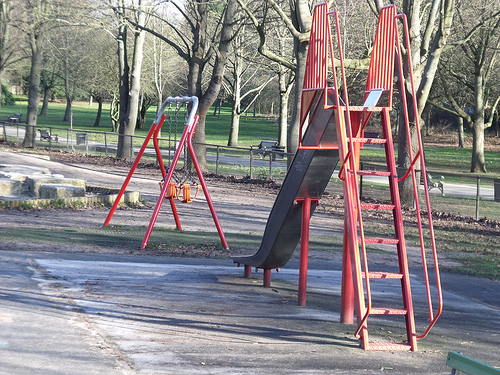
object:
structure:
[0, 162, 141, 211]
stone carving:
[8, 173, 87, 199]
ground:
[0, 97, 497, 375]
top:
[444, 348, 500, 375]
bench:
[443, 345, 500, 374]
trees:
[95, 45, 108, 78]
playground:
[1, 124, 500, 375]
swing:
[97, 94, 230, 251]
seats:
[158, 181, 182, 199]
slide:
[228, 0, 447, 356]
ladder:
[292, 2, 446, 355]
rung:
[347, 137, 387, 144]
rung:
[356, 170, 391, 176]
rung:
[354, 204, 395, 210]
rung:
[361, 271, 405, 279]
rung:
[365, 307, 408, 315]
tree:
[0, 0, 69, 151]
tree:
[82, 0, 165, 162]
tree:
[99, 0, 258, 178]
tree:
[238, 1, 368, 178]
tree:
[266, 19, 294, 153]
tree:
[221, 1, 281, 148]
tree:
[363, 0, 462, 209]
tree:
[439, 0, 499, 173]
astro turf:
[0, 217, 500, 278]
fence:
[0, 120, 500, 228]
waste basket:
[74, 132, 88, 145]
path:
[0, 121, 500, 201]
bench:
[249, 139, 286, 160]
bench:
[37, 128, 59, 144]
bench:
[413, 168, 446, 197]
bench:
[0, 113, 25, 127]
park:
[0, 0, 493, 373]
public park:
[0, 108, 500, 375]